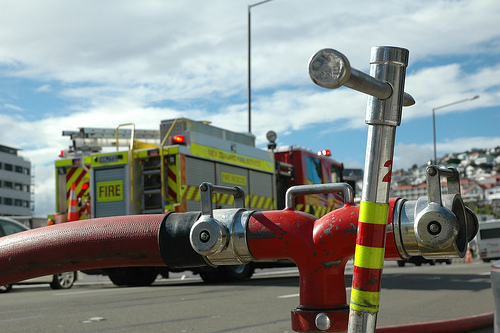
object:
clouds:
[0, 0, 499, 93]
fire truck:
[54, 117, 345, 286]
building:
[0, 145, 33, 221]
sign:
[97, 179, 124, 201]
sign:
[222, 171, 246, 186]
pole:
[430, 108, 437, 164]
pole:
[246, 5, 251, 133]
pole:
[344, 44, 409, 333]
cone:
[464, 248, 471, 262]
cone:
[65, 178, 80, 219]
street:
[0, 249, 499, 332]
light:
[172, 134, 184, 143]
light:
[326, 149, 333, 156]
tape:
[351, 243, 384, 269]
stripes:
[64, 166, 76, 181]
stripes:
[166, 185, 176, 201]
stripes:
[224, 194, 232, 205]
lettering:
[99, 185, 121, 198]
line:
[274, 280, 352, 298]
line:
[74, 269, 303, 288]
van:
[475, 217, 500, 263]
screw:
[309, 48, 416, 106]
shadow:
[249, 272, 490, 292]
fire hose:
[0, 209, 169, 290]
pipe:
[291, 261, 347, 332]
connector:
[192, 180, 257, 269]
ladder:
[63, 128, 160, 140]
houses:
[393, 176, 483, 200]